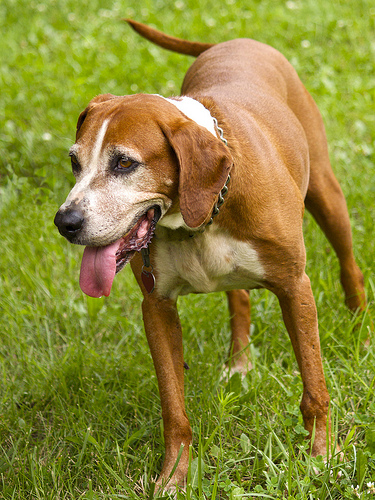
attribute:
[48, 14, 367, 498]
dog — brown, white, reddish-brown, walking, standing, panting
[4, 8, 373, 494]
grass — green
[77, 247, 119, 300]
tongue — pink, hanging out, sticking out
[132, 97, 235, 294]
collar — metal, chained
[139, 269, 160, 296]
heart — red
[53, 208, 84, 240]
nose — black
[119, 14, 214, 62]
tail — brown, waggling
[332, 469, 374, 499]
flowers — white, yellow